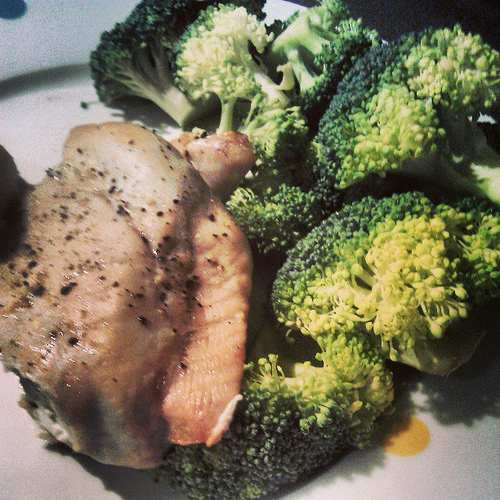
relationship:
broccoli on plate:
[117, 10, 496, 481] [9, 0, 497, 495]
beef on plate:
[0, 121, 252, 469] [9, 0, 497, 495]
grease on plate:
[377, 406, 438, 462] [9, 0, 497, 495]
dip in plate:
[5, 53, 91, 113] [9, 0, 497, 495]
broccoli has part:
[117, 10, 496, 481] [180, 19, 291, 138]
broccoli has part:
[117, 10, 496, 481] [235, 26, 499, 415]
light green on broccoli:
[252, 31, 492, 382] [117, 10, 496, 481]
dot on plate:
[378, 406, 440, 461] [9, 0, 497, 495]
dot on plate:
[3, 3, 31, 21] [9, 0, 497, 495]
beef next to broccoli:
[0, 121, 252, 469] [117, 10, 496, 481]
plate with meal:
[9, 0, 497, 495] [3, 1, 498, 487]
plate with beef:
[9, 0, 497, 495] [0, 121, 252, 469]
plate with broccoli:
[9, 0, 497, 495] [117, 10, 496, 481]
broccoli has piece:
[117, 10, 496, 481] [175, 8, 276, 98]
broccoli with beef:
[117, 10, 496, 481] [0, 121, 252, 469]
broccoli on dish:
[117, 10, 496, 481] [7, 6, 495, 491]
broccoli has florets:
[117, 10, 496, 481] [181, 2, 373, 155]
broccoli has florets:
[117, 10, 496, 481] [166, 23, 500, 487]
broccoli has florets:
[117, 10, 496, 481] [161, 198, 499, 499]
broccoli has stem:
[85, 0, 496, 499] [425, 111, 500, 203]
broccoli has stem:
[85, 0, 496, 499] [135, 41, 209, 119]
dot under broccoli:
[379, 413, 430, 456] [117, 10, 496, 481]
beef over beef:
[0, 121, 252, 469] [3, 112, 268, 444]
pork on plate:
[6, 114, 266, 435] [9, 0, 497, 495]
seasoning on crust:
[2, 134, 232, 368] [1, 120, 191, 373]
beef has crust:
[0, 121, 252, 469] [1, 120, 191, 373]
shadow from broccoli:
[400, 363, 499, 435] [117, 10, 496, 481]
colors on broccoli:
[86, 5, 500, 495] [117, 10, 496, 481]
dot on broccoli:
[379, 413, 430, 456] [117, 10, 496, 481]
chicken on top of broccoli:
[4, 117, 268, 450] [117, 10, 496, 481]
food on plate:
[7, 1, 493, 478] [9, 0, 497, 495]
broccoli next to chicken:
[117, 10, 496, 481] [4, 117, 268, 450]